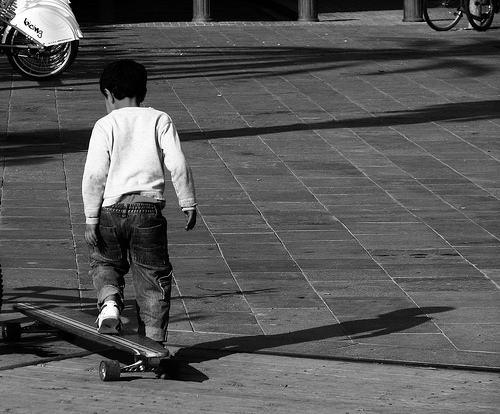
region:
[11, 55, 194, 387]
small boy playing with skateboard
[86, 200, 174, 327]
child wearing pull on jeans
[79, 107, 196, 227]
child wearing long sleeved shirt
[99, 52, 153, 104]
child with jet black hair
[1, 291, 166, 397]
wooden skateboard with boy's foot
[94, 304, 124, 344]
white tennis shoe worn by boy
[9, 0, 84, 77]
fleet of white motorcycles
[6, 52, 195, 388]
young boy on a skateboard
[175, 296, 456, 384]
shadow of the young boy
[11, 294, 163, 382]
skateboard with white stripe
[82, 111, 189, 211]
long sleeve shirt child is wearing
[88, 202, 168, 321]
jeans the boy is wearing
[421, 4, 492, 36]
bicycle on the right side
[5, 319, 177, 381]
black wheels on the skateboard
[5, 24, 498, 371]
walkway child is on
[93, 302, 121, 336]
white shoe the boy is wearing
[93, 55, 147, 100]
dark hair of the child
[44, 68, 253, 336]
a boy that is outside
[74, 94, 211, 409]
a boy on a skateboard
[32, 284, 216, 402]
a skateboard on teh ground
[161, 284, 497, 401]
a shadow of a boy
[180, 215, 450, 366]
a shadow on the ground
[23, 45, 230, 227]
a boy with dark hair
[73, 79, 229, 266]
a boy wearing a sweater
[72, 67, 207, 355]
a boy wearing pants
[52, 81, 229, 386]
a boy wearing belt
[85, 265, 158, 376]
a boy wearing shoe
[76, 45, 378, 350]
this is grayscale style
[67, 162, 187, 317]
the boy has jeans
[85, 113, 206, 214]
the boy has white sweater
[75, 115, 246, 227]
the sweater is long sleeved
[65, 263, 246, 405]
this is a longboard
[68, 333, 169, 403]
these are wheels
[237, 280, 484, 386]
this is the shadow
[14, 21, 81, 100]
this is a motorbike